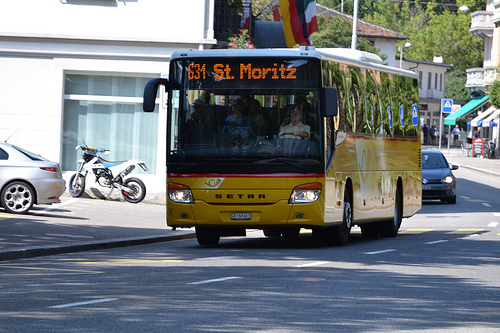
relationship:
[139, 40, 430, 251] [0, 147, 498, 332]
bus on road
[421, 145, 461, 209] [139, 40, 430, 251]
car behind bus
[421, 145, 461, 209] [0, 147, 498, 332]
car on road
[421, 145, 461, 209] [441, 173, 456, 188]
car has headlight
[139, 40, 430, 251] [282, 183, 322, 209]
bus has headlight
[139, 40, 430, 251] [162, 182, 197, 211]
bus has headlight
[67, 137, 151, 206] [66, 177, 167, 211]
motorcycle on sidewalk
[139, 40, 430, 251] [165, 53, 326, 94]
bus has marquee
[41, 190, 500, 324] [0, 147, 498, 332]
line on road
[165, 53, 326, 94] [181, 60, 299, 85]
marquee has destination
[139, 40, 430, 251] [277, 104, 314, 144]
bus has bus driver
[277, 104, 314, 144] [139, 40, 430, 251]
bus driver steering bus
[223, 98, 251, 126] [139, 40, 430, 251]
passenger on bus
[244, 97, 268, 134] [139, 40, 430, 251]
passenger on bus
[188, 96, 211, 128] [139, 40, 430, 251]
passenger on bus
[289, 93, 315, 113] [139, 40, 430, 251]
passenger on bus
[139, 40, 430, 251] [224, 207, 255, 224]
bus has license plate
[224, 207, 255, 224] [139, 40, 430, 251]
license plate on front of bus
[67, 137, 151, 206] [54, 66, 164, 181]
motorcycle near window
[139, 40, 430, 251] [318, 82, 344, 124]
bus has side view mirror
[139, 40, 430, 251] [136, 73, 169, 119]
bus has side view mirror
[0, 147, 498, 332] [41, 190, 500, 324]
road has line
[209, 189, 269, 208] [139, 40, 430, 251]
bus company name on bus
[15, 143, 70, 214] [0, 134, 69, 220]
back of car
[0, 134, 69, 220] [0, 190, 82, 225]
car in lot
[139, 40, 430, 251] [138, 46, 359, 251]
bus has front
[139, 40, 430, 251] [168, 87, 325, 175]
bus has windshield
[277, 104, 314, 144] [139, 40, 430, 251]
bus driver on bus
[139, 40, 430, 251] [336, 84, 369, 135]
bus has window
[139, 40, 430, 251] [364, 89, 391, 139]
bus has window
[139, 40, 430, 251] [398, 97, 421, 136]
bus has window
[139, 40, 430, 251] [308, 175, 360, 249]
bus has wheel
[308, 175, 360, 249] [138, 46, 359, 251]
wheel on front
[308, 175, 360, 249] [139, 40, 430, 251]
wheel on front of bus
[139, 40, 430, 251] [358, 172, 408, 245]
bus has wheel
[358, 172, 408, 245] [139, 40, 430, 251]
wheel on rear of bus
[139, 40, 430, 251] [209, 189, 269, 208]
bus has logo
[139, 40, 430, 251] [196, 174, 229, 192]
bus has decal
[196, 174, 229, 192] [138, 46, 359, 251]
decal on front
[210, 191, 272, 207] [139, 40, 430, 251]
logo on bus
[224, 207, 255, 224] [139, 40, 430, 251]
license plate on bus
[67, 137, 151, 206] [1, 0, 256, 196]
motorcycle next to building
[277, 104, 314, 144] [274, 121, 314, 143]
bus driver has shirt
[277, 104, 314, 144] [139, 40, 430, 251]
bus driver driving bus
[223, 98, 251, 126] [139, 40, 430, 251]
passenger sitting on bus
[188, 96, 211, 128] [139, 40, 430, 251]
passenger sitting on bus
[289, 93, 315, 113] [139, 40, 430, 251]
passenger sitting on bus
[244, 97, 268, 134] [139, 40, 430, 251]
passenger sitting on bus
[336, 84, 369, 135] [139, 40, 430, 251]
window on side of bus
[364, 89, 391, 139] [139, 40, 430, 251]
window on side of bus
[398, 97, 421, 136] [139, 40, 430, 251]
window on side of bus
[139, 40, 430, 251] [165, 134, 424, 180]
bus has stripe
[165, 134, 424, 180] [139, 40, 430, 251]
stripe on side of bus